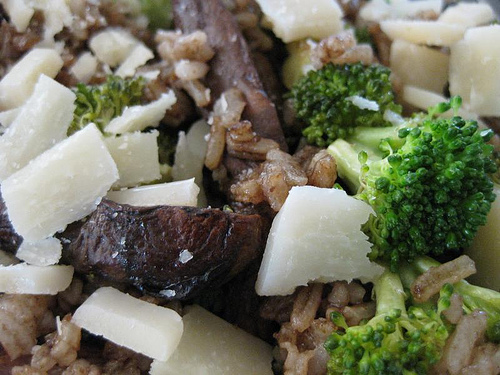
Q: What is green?
A: The broccoli.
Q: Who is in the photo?
A: Nobody.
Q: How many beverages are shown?
A: Zero.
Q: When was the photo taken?
A: Before the meal.